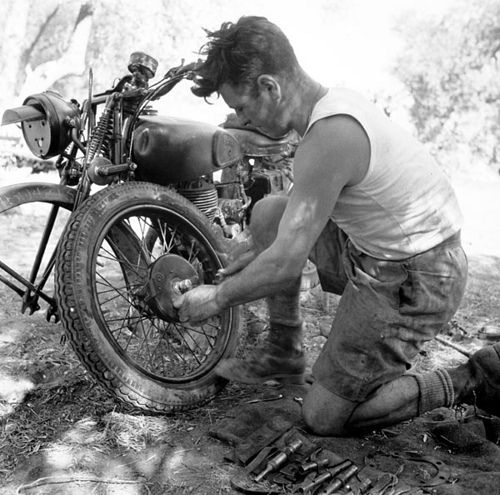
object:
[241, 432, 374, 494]
tool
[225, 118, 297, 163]
seat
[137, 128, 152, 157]
dent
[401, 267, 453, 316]
pocket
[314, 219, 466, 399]
shorts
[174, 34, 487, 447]
man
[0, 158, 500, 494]
ground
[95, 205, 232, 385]
silver spokes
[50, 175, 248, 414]
tire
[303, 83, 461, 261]
shirt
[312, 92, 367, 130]
ground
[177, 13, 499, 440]
man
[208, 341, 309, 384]
boots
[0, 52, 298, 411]
bike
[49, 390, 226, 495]
shade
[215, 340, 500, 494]
blanket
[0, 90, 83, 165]
bike headlight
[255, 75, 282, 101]
ear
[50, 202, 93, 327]
treads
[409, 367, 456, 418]
sock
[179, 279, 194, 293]
bolt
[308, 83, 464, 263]
tank top